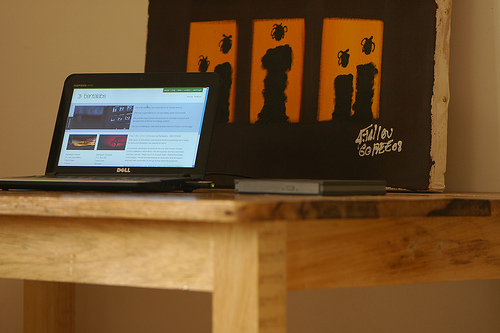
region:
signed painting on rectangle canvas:
[144, 1, 449, 189]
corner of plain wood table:
[0, 189, 498, 331]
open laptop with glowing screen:
[0, 72, 216, 190]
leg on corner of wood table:
[0, 189, 497, 330]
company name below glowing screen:
[44, 73, 219, 175]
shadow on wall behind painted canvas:
[146, 0, 473, 192]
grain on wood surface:
[288, 217, 497, 286]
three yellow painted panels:
[185, 16, 382, 125]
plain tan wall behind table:
[1, 0, 498, 331]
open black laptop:
[5, 63, 232, 193]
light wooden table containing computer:
[1, 175, 499, 318]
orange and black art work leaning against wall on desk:
[141, 2, 455, 184]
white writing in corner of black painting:
[354, 121, 401, 161]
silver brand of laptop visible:
[110, 164, 135, 176]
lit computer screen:
[57, 83, 205, 168]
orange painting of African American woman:
[248, 16, 305, 118]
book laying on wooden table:
[233, 176, 391, 193]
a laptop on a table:
[12, 65, 267, 280]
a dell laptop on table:
[57, 48, 200, 223]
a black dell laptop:
[29, 48, 206, 232]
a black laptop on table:
[24, 56, 211, 261]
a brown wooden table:
[24, 110, 431, 331]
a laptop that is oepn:
[75, 61, 231, 222]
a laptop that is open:
[42, 65, 219, 200]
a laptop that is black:
[62, 72, 208, 197]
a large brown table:
[47, 150, 376, 329]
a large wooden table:
[134, 130, 403, 322]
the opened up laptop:
[0, 71, 235, 193]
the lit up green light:
[208, 180, 216, 188]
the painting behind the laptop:
[1, 0, 452, 190]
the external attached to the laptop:
[0, 71, 389, 196]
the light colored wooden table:
[0, 187, 498, 329]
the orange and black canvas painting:
[143, 0, 453, 191]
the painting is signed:
[143, 0, 452, 191]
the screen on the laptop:
[0, 72, 222, 189]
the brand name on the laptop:
[0, 71, 225, 193]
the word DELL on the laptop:
[3, 71, 230, 193]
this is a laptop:
[13, 48, 234, 226]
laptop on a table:
[5, 30, 477, 327]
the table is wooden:
[5, 137, 495, 329]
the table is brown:
[0, 162, 490, 322]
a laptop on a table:
[5, 63, 276, 316]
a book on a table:
[219, 161, 400, 216]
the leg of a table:
[203, 228, 297, 331]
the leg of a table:
[11, 272, 83, 332]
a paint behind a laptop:
[128, 1, 462, 200]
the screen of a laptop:
[41, 61, 226, 175]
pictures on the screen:
[56, 85, 142, 158]